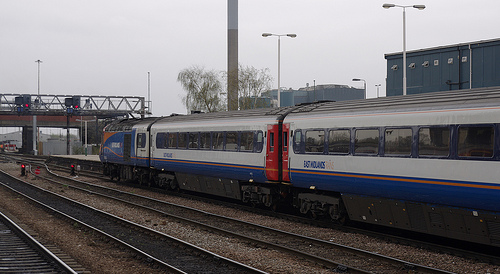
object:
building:
[382, 36, 500, 96]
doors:
[263, 122, 280, 181]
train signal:
[17, 163, 29, 175]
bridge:
[1, 91, 151, 129]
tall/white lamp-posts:
[261, 31, 298, 110]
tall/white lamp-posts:
[381, 2, 429, 97]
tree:
[176, 66, 225, 113]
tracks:
[0, 170, 274, 273]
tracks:
[1, 213, 85, 273]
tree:
[222, 64, 272, 108]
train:
[96, 84, 500, 251]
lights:
[69, 105, 79, 110]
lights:
[22, 102, 31, 108]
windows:
[455, 124, 498, 161]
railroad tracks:
[9, 157, 310, 226]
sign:
[33, 167, 45, 175]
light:
[69, 163, 75, 168]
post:
[68, 160, 77, 175]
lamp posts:
[259, 31, 303, 110]